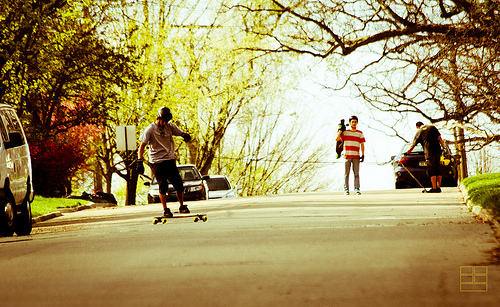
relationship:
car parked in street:
[0, 103, 35, 238] [2, 182, 498, 305]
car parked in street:
[203, 175, 242, 200] [2, 182, 498, 305]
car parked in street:
[145, 160, 209, 202] [2, 182, 498, 305]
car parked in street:
[391, 139, 458, 189] [2, 182, 498, 305]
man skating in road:
[138, 106, 192, 218] [67, 255, 399, 304]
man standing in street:
[336, 115, 366, 196] [66, 205, 476, 303]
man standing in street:
[403, 121, 445, 193] [2, 182, 498, 305]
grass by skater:
[467, 169, 500, 206] [405, 117, 452, 199]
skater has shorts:
[140, 123, 184, 184] [143, 156, 188, 191]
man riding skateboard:
[139, 104, 213, 224] [154, 210, 214, 225]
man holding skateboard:
[336, 109, 375, 191] [149, 202, 210, 228]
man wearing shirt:
[336, 115, 366, 196] [339, 122, 366, 162]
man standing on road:
[404, 120, 449, 192] [2, 185, 498, 304]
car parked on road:
[0, 103, 35, 238] [186, 175, 428, 285]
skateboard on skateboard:
[152, 213, 208, 225] [150, 210, 215, 227]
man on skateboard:
[138, 106, 192, 218] [150, 208, 207, 225]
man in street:
[138, 106, 192, 218] [2, 182, 498, 305]